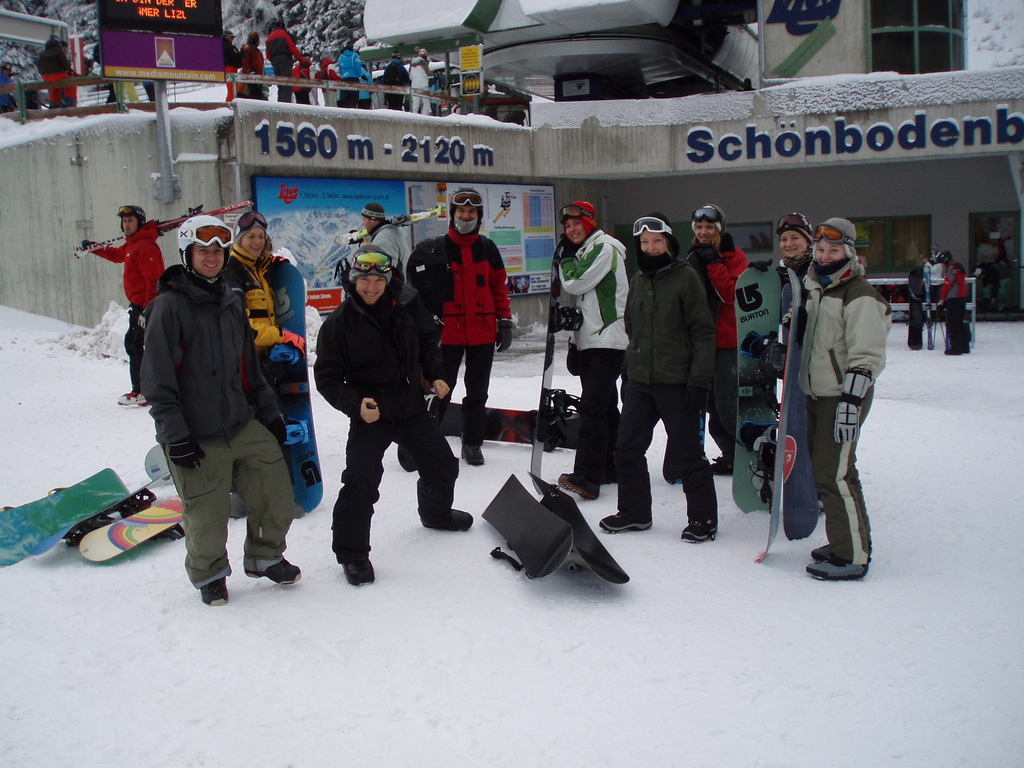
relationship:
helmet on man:
[157, 212, 260, 288] [142, 216, 316, 590]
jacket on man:
[138, 273, 284, 447] [142, 216, 316, 590]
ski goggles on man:
[343, 250, 401, 280] [309, 247, 483, 590]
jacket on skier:
[549, 240, 632, 359] [520, 194, 642, 490]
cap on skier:
[549, 196, 601, 232] [520, 194, 642, 490]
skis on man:
[106, 188, 266, 242] [91, 204, 162, 376]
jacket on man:
[88, 217, 166, 307] [91, 204, 162, 376]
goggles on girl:
[632, 217, 674, 237] [603, 207, 720, 552]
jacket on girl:
[603, 260, 728, 391] [603, 207, 720, 552]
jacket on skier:
[88, 203, 175, 339] [88, 203, 175, 339]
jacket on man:
[139, 273, 286, 447] [142, 216, 297, 603]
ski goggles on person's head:
[344, 251, 403, 281] [344, 251, 402, 310]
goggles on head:
[626, 215, 671, 238] [630, 210, 670, 253]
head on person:
[630, 210, 670, 253] [601, 215, 720, 530]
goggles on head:
[808, 225, 853, 245] [811, 219, 854, 267]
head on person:
[811, 219, 854, 267] [787, 225, 882, 579]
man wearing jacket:
[316, 247, 474, 581] [319, 308, 449, 423]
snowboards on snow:
[483, 475, 624, 589] [506, 580, 691, 658]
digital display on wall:
[88, 4, 250, 96] [95, 1, 227, 81]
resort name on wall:
[666, 101, 1021, 182] [235, 91, 985, 167]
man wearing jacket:
[80, 204, 172, 407] [88, 197, 181, 359]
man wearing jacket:
[80, 204, 172, 407] [92, 200, 175, 322]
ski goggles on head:
[183, 222, 242, 255] [176, 222, 249, 308]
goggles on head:
[689, 206, 722, 222] [693, 204, 726, 246]